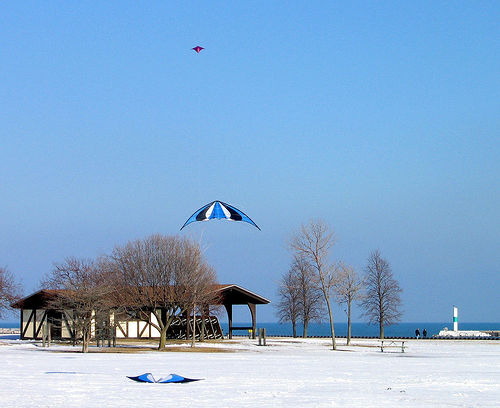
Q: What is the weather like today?
A: It is clear.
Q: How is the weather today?
A: It is clear.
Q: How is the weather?
A: It is clear.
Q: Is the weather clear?
A: Yes, it is clear.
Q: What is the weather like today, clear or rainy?
A: It is clear.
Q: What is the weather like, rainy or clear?
A: It is clear.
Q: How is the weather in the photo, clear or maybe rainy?
A: It is clear.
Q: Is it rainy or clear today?
A: It is clear.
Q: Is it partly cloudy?
A: No, it is clear.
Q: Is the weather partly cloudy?
A: No, it is clear.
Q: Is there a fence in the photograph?
A: No, there are no fences.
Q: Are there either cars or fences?
A: No, there are no fences or cars.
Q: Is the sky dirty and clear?
A: No, the sky is clear but clean.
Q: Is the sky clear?
A: Yes, the sky is clear.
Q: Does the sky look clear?
A: Yes, the sky is clear.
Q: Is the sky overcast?
A: No, the sky is clear.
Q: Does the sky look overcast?
A: No, the sky is clear.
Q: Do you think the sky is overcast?
A: No, the sky is clear.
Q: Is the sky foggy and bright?
A: No, the sky is bright but clear.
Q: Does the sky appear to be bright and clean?
A: Yes, the sky is bright and clean.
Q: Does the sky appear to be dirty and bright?
A: No, the sky is bright but clean.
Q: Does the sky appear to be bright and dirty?
A: No, the sky is bright but clean.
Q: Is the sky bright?
A: Yes, the sky is bright.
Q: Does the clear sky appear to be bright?
A: Yes, the sky is bright.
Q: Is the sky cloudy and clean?
A: No, the sky is clean but clear.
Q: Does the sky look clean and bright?
A: Yes, the sky is clean and bright.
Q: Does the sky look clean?
A: Yes, the sky is clean.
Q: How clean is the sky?
A: The sky is clean.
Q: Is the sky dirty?
A: No, the sky is clean.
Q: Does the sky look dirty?
A: No, the sky is clean.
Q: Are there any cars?
A: No, there are no cars.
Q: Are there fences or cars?
A: No, there are no cars or fences.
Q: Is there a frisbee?
A: No, there are no frisbees.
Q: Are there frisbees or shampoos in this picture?
A: No, there are no frisbees or shampoos.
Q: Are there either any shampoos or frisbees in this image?
A: No, there are no frisbees or shampoos.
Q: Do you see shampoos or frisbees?
A: No, there are no frisbees or shampoos.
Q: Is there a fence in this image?
A: No, there are no fences.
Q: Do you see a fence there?
A: No, there are no fences.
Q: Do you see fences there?
A: No, there are no fences.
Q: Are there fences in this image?
A: No, there are no fences.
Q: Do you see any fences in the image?
A: No, there are no fences.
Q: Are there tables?
A: Yes, there is a table.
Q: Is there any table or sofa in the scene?
A: Yes, there is a table.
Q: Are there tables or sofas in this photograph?
A: Yes, there is a table.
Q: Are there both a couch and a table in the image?
A: No, there is a table but no couches.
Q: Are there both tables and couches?
A: No, there is a table but no couches.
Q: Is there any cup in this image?
A: No, there are no cups.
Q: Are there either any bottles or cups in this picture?
A: No, there are no cups or bottles.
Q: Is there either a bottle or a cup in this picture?
A: No, there are no cups or bottles.